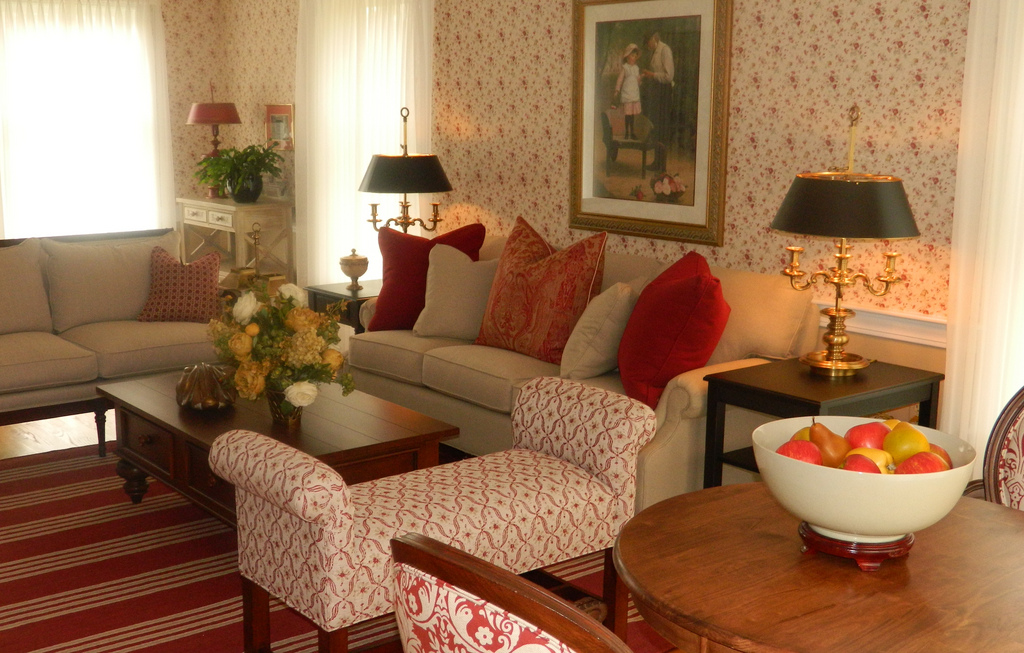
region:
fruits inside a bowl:
[752, 416, 983, 559]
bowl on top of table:
[609, 414, 1022, 649]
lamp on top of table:
[714, 98, 934, 481]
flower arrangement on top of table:
[98, 274, 465, 503]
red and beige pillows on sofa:
[375, 215, 740, 431]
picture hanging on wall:
[566, 4, 741, 245]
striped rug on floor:
[2, 437, 799, 649]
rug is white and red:
[0, 433, 734, 650]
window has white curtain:
[288, 4, 440, 330]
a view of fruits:
[711, 385, 974, 575]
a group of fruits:
[739, 357, 964, 503]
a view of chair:
[316, 528, 589, 647]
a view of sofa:
[182, 363, 598, 573]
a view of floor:
[94, 484, 197, 647]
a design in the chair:
[452, 579, 541, 644]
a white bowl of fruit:
[762, 398, 977, 570]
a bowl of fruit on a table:
[635, 401, 990, 618]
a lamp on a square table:
[772, 152, 925, 400]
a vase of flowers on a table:
[221, 273, 358, 430]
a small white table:
[177, 191, 289, 294]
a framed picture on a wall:
[554, 7, 754, 239]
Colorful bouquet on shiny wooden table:
[198, 266, 355, 422]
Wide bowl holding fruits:
[742, 402, 986, 559]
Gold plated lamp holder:
[803, 301, 879, 393]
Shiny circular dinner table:
[627, 552, 1007, 630]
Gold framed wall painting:
[550, 9, 744, 245]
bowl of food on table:
[692, 376, 984, 595]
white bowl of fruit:
[727, 401, 991, 560]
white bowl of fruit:
[712, 394, 992, 551]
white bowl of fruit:
[716, 376, 980, 550]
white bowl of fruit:
[721, 397, 993, 546]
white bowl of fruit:
[715, 373, 987, 557]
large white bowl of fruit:
[752, 415, 977, 564]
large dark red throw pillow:
[613, 247, 734, 400]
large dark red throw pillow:
[367, 222, 482, 328]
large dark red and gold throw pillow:
[474, 211, 605, 364]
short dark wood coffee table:
[98, 367, 454, 530]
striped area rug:
[2, 442, 673, 649]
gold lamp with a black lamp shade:
[357, 104, 449, 237]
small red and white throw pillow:
[145, 246, 218, 323]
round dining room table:
[606, 472, 1021, 641]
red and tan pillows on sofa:
[377, 206, 488, 331]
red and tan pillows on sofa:
[468, 203, 605, 355]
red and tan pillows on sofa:
[558, 262, 698, 379]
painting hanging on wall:
[544, 4, 731, 226]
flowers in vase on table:
[222, 253, 341, 405]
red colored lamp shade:
[190, 66, 254, 133]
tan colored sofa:
[0, 221, 137, 370]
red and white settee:
[272, 376, 573, 586]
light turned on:
[748, 119, 917, 370]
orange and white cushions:
[438, 235, 812, 384]